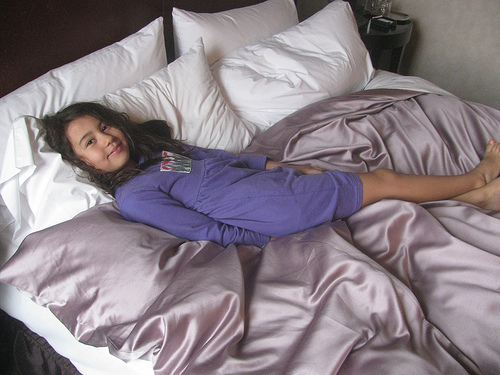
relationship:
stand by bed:
[361, 10, 418, 64] [42, 40, 485, 367]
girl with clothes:
[45, 99, 496, 256] [112, 153, 373, 206]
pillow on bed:
[231, 4, 361, 125] [42, 40, 485, 367]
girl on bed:
[45, 99, 496, 256] [42, 40, 485, 367]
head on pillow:
[46, 84, 148, 185] [231, 4, 361, 125]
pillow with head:
[231, 4, 361, 125] [46, 84, 148, 185]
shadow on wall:
[416, 24, 435, 73] [417, 38, 479, 70]